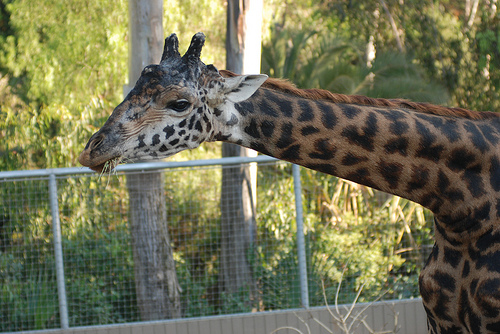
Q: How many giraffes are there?
A: One.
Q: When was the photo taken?
A: Day time.